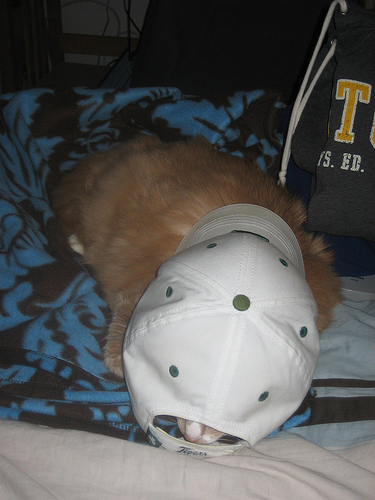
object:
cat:
[54, 132, 341, 447]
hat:
[121, 199, 323, 459]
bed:
[1, 1, 375, 499]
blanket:
[1, 84, 374, 444]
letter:
[333, 77, 372, 145]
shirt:
[282, 2, 374, 239]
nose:
[179, 419, 205, 446]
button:
[232, 293, 251, 312]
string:
[273, 0, 348, 186]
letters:
[318, 149, 363, 170]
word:
[175, 445, 209, 459]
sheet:
[1, 424, 374, 499]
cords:
[99, 3, 141, 85]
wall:
[42, 2, 149, 65]